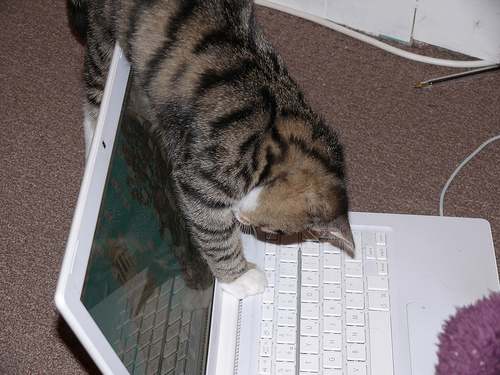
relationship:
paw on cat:
[213, 260, 269, 300] [178, 110, 323, 237]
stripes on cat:
[132, 0, 263, 127] [63, 0, 396, 302]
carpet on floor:
[355, 100, 430, 190] [347, 52, 498, 207]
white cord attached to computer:
[442, 146, 484, 207] [53, 39, 500, 375]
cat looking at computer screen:
[66, 1, 357, 301] [82, 72, 217, 374]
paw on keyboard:
[213, 260, 269, 300] [256, 228, 393, 374]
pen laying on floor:
[419, 67, 496, 92] [0, 1, 498, 369]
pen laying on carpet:
[420, 67, 500, 87] [3, 6, 498, 372]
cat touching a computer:
[66, 1, 357, 301] [53, 39, 500, 375]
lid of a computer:
[48, 41, 230, 373] [53, 39, 500, 375]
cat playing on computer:
[66, 1, 357, 301] [53, 39, 500, 375]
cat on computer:
[109, 19, 427, 339] [25, 31, 487, 371]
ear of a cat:
[320, 209, 359, 256] [66, 1, 357, 301]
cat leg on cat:
[171, 150, 267, 280] [66, 1, 357, 301]